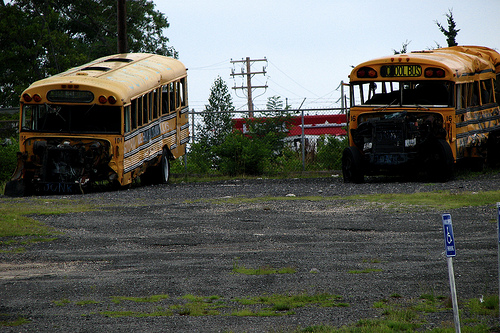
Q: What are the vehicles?
A: School Buses.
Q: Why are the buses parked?
A: The buses are broken.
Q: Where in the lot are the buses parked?
A: By the fence.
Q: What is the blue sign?
A: Handicapped parking.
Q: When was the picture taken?
A: Daytime.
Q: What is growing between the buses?
A: A bush.